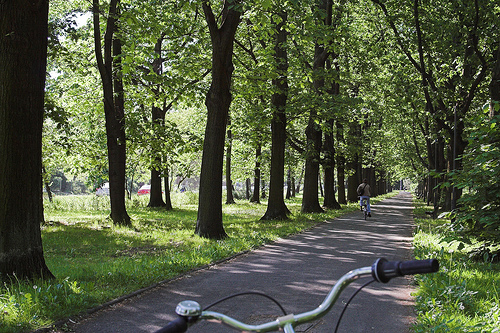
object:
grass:
[0, 194, 343, 333]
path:
[58, 191, 416, 331]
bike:
[152, 252, 439, 332]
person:
[356, 179, 371, 218]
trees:
[185, 5, 255, 242]